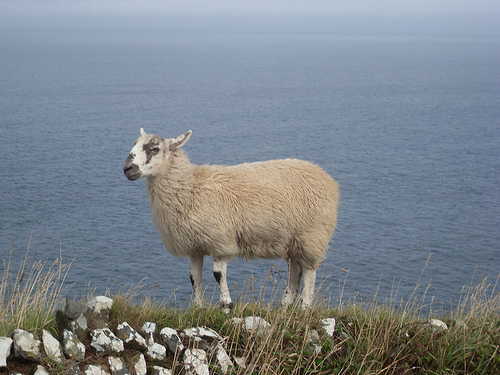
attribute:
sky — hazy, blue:
[3, 2, 499, 50]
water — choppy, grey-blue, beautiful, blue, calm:
[3, 33, 500, 314]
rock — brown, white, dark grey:
[160, 324, 186, 356]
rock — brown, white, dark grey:
[179, 326, 227, 351]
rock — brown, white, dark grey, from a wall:
[89, 327, 128, 355]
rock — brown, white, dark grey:
[35, 328, 67, 366]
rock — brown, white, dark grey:
[75, 294, 115, 334]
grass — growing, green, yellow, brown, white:
[4, 230, 340, 375]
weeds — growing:
[403, 331, 490, 373]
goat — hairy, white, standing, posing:
[121, 125, 341, 320]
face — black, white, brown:
[119, 133, 169, 185]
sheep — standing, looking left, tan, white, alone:
[124, 125, 344, 320]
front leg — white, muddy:
[189, 248, 208, 317]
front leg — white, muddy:
[212, 255, 236, 316]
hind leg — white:
[300, 257, 318, 312]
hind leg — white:
[279, 255, 304, 308]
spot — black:
[188, 271, 199, 287]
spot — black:
[213, 269, 224, 285]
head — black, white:
[123, 126, 193, 184]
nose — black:
[121, 163, 134, 174]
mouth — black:
[128, 172, 141, 181]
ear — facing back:
[170, 128, 196, 151]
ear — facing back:
[138, 126, 147, 137]